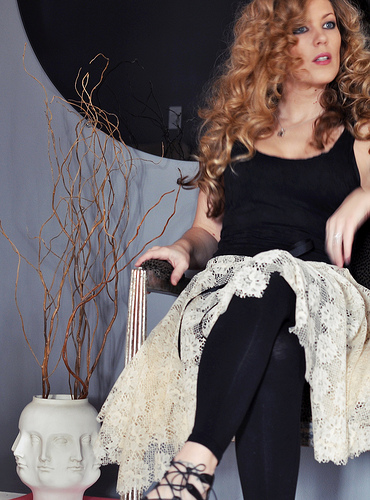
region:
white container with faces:
[10, 387, 105, 498]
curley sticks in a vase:
[9, 88, 124, 498]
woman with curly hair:
[190, 0, 368, 217]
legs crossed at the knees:
[151, 267, 309, 498]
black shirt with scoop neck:
[215, 97, 355, 260]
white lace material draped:
[297, 261, 368, 461]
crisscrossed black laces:
[143, 450, 218, 498]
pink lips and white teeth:
[309, 50, 332, 66]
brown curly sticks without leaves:
[11, 85, 129, 398]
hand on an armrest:
[124, 242, 199, 328]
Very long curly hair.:
[178, 8, 294, 210]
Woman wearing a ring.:
[330, 229, 345, 243]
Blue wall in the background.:
[3, 91, 40, 208]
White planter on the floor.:
[13, 389, 108, 496]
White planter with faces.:
[9, 393, 106, 490]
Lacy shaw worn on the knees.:
[117, 254, 242, 429]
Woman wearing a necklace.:
[269, 119, 301, 144]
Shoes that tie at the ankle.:
[142, 461, 220, 499]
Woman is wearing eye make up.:
[282, 12, 340, 42]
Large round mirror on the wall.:
[116, 16, 206, 77]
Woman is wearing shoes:
[128, 452, 218, 497]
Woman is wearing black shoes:
[134, 452, 220, 497]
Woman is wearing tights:
[187, 266, 311, 498]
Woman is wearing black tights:
[179, 271, 311, 498]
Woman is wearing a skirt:
[94, 247, 368, 495]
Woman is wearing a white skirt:
[91, 242, 369, 494]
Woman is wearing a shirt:
[201, 87, 368, 279]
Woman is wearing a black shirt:
[214, 105, 366, 277]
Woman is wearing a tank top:
[214, 102, 369, 283]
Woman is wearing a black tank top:
[210, 102, 364, 266]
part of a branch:
[77, 361, 85, 369]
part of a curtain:
[311, 429, 333, 454]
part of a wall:
[306, 464, 318, 471]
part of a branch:
[75, 369, 86, 381]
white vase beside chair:
[9, 384, 103, 498]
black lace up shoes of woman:
[137, 457, 220, 498]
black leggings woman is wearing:
[188, 277, 306, 499]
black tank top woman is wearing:
[211, 108, 364, 259]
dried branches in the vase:
[25, 48, 188, 394]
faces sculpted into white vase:
[9, 396, 106, 495]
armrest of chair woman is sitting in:
[130, 254, 202, 300]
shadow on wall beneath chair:
[296, 446, 356, 491]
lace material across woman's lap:
[100, 247, 369, 484]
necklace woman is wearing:
[269, 114, 294, 135]